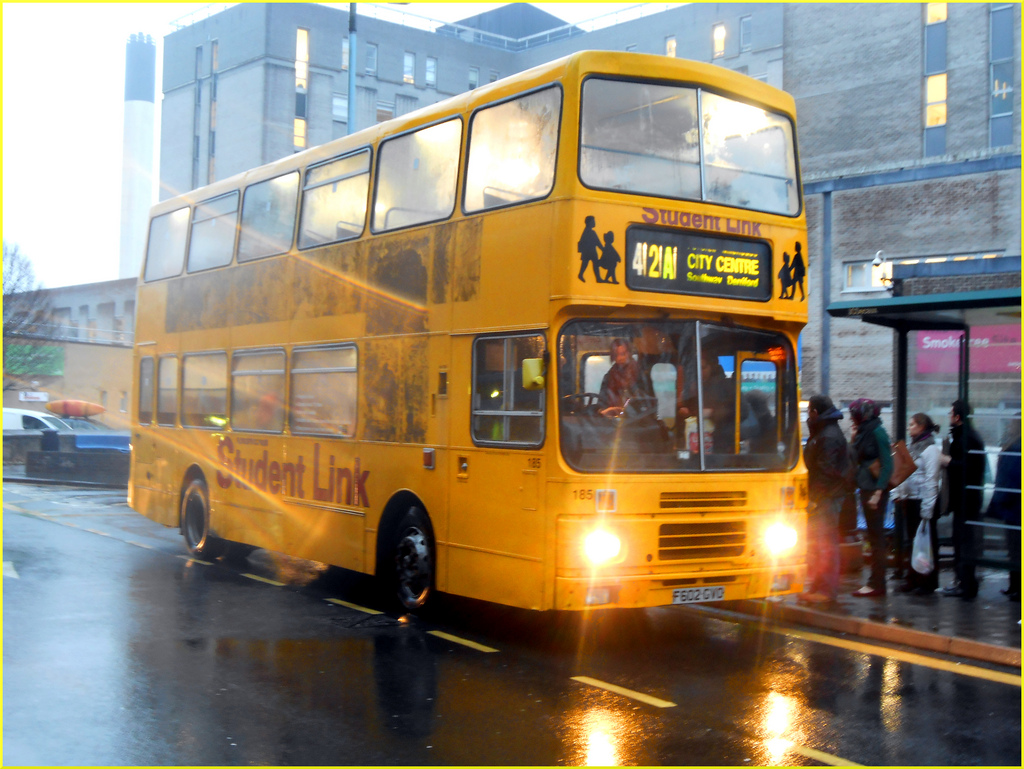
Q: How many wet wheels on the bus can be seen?
A: Two of four.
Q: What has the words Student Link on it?
A: The bus.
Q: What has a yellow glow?
A: The lights in the building.